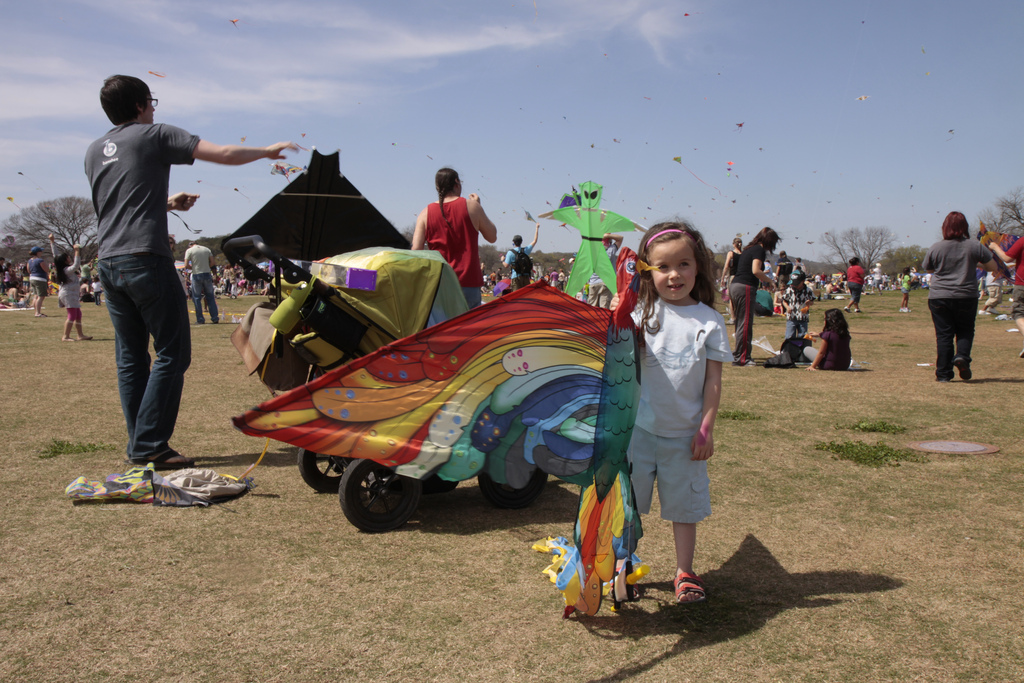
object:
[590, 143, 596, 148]
kite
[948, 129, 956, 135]
kite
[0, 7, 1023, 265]
sky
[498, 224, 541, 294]
person